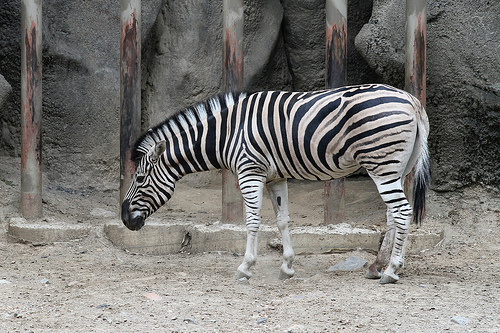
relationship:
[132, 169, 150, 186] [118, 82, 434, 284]
eye of animal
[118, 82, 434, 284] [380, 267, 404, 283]
animal has left foot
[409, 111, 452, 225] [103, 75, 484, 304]
tail on zebra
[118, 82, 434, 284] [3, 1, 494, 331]
animal in captivity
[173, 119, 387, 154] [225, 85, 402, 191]
stripes on body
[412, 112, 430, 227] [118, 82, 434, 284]
tail of animal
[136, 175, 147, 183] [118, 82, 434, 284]
eye of animal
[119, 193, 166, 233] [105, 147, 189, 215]
black nose on face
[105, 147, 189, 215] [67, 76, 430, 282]
face of zebra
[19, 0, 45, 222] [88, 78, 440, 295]
bars behind zebra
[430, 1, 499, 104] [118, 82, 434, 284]
rock wall behind animal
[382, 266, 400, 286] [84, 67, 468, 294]
back foot of zebra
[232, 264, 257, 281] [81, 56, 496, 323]
foot of zebra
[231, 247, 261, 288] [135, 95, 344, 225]
foot on zebra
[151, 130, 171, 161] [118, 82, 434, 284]
left of animal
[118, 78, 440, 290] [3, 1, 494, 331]
animal in captivity